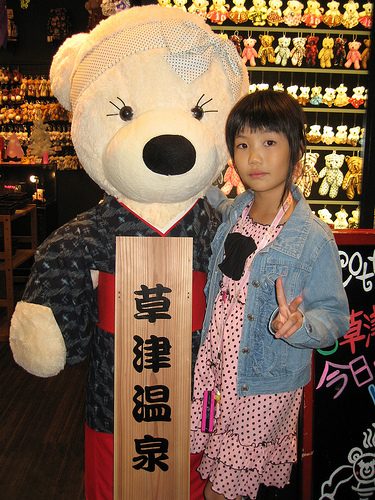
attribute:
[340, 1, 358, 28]
teddy bear — hung up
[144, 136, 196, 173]
nose — black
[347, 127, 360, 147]
teddy bear — hung up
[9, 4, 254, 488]
bear — teddy, hung up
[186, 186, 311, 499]
dress — black, dotted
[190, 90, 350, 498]
girl — little, posing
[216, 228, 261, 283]
bow — black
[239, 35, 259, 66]
teddy bear — hung up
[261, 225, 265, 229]
dots — black, polka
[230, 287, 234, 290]
dots — black, polka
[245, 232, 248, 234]
dots — black, polka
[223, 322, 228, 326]
dots — black, polka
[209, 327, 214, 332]
dots — black, polka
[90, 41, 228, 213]
bear — large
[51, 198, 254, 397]
shirt — black, grey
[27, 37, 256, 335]
bear — hung up, teddy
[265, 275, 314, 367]
sign — peace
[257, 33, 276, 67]
bear — teddy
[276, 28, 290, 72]
bear — teddy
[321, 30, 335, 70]
bear — teddy